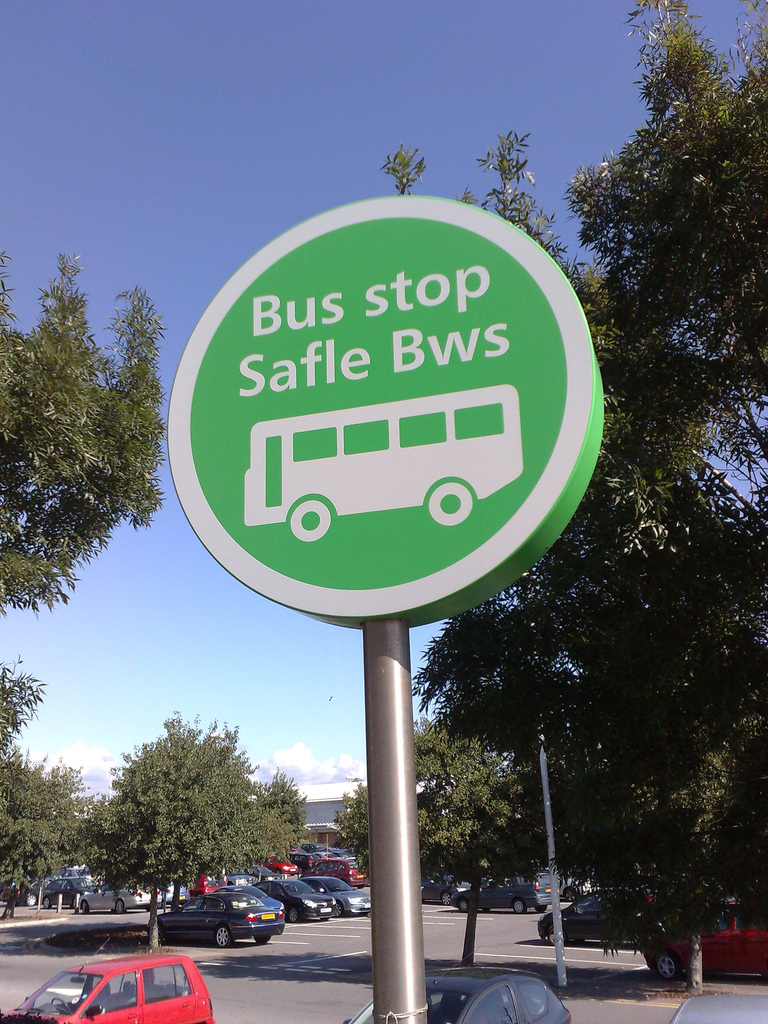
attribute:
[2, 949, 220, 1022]
vehicle — red 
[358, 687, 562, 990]
tree — green , large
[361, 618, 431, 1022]
metal pole — thin, silver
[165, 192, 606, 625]
sign — round , green , white 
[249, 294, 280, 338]
letter — white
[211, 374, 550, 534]
bus — white 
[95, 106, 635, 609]
sign — green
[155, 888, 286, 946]
car — dark gray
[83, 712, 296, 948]
tree — green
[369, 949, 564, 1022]
car — gray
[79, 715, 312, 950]
tree — large, green